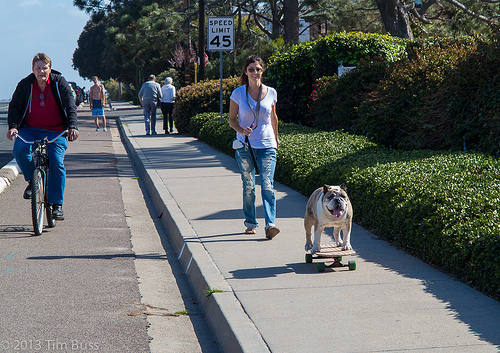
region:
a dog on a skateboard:
[294, 165, 383, 260]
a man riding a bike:
[7, 42, 84, 241]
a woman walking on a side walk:
[216, 44, 298, 245]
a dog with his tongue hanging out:
[285, 171, 390, 291]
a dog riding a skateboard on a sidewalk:
[286, 145, 386, 342]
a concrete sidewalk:
[163, 128, 203, 247]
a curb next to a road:
[118, 137, 200, 352]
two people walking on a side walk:
[138, 66, 178, 135]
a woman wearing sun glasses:
[230, 55, 280, 105]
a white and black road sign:
[190, 5, 248, 74]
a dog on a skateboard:
[279, 154, 404, 311]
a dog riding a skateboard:
[282, 161, 402, 331]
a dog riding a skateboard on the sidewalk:
[286, 159, 389, 301]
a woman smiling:
[182, 45, 287, 224]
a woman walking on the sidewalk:
[222, 48, 312, 274]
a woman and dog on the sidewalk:
[212, 28, 372, 285]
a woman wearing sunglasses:
[222, 39, 292, 239]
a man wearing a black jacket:
[14, 34, 120, 236]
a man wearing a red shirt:
[10, 40, 107, 209]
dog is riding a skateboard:
[293, 183, 384, 309]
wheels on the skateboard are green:
[297, 255, 363, 279]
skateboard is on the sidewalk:
[287, 182, 393, 310]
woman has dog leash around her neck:
[227, 42, 273, 164]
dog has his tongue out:
[315, 194, 368, 226]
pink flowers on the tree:
[173, 35, 210, 66]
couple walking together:
[138, 59, 202, 140]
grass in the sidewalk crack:
[133, 266, 268, 323]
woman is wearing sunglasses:
[245, 49, 271, 80]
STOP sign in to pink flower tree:
[202, 43, 223, 69]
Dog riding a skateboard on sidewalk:
[293, 177, 361, 270]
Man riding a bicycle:
[9, 49, 79, 237]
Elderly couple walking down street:
[141, 69, 177, 136]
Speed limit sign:
[205, 13, 234, 122]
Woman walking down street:
[225, 54, 282, 241]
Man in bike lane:
[85, 73, 109, 136]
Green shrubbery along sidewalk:
[365, 123, 498, 273]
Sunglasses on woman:
[246, 60, 265, 77]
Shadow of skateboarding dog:
[227, 259, 332, 282]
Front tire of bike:
[26, 166, 49, 235]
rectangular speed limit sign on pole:
[207, 15, 234, 131]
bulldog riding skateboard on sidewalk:
[303, 181, 358, 275]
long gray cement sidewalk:
[108, 96, 497, 350]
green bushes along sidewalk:
[189, 109, 498, 297]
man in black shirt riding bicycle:
[7, 52, 77, 237]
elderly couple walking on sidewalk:
[136, 73, 176, 133]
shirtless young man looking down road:
[86, 74, 110, 133]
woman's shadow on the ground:
[24, 228, 271, 263]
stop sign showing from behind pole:
[194, 51, 209, 70]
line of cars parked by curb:
[57, 80, 90, 110]